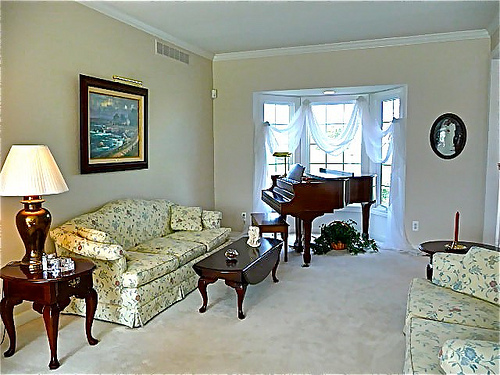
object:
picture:
[76, 73, 151, 175]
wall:
[1, 0, 215, 325]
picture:
[429, 111, 468, 161]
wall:
[210, 31, 490, 257]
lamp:
[0, 143, 72, 273]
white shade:
[0, 143, 71, 199]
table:
[191, 236, 286, 320]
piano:
[262, 168, 380, 268]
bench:
[249, 212, 290, 262]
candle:
[224, 247, 240, 260]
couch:
[400, 245, 499, 374]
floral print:
[464, 346, 479, 361]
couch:
[49, 194, 235, 327]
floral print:
[152, 239, 165, 248]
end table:
[0, 255, 103, 372]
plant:
[306, 218, 381, 255]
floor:
[0, 233, 431, 374]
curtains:
[264, 100, 305, 157]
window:
[250, 84, 409, 242]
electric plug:
[411, 219, 420, 232]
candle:
[443, 209, 469, 251]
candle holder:
[444, 239, 467, 252]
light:
[112, 75, 142, 88]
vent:
[154, 39, 190, 66]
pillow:
[168, 203, 204, 232]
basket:
[329, 240, 348, 250]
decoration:
[245, 225, 262, 248]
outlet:
[239, 211, 247, 224]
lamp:
[272, 151, 292, 179]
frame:
[75, 70, 148, 177]